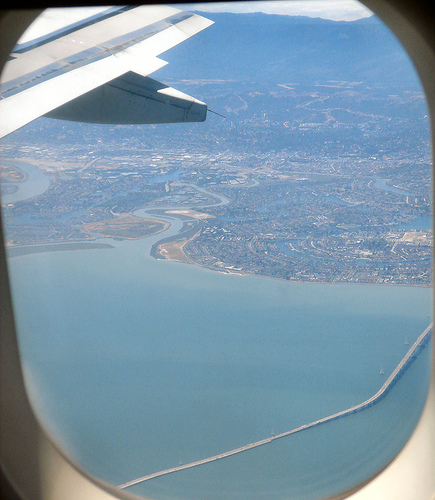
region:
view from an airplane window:
[16, 2, 424, 494]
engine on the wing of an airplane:
[47, 58, 212, 141]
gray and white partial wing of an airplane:
[2, 5, 219, 136]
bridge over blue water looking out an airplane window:
[117, 317, 433, 486]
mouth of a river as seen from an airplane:
[99, 219, 166, 263]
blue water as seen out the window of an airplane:
[118, 285, 364, 490]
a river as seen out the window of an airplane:
[136, 171, 232, 259]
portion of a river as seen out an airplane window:
[2, 158, 49, 210]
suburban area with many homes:
[194, 156, 423, 284]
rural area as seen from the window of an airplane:
[156, 26, 400, 148]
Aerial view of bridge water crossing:
[118, 301, 429, 493]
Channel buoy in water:
[373, 360, 388, 380]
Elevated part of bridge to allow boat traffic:
[397, 313, 429, 382]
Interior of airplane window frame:
[1, 229, 431, 499]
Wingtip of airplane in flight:
[1, 3, 229, 145]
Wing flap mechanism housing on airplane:
[42, 69, 218, 126]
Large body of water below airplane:
[13, 241, 430, 497]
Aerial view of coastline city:
[11, 143, 434, 295]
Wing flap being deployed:
[10, 4, 216, 148]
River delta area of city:
[62, 166, 434, 297]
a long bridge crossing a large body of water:
[105, 336, 414, 494]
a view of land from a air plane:
[105, 174, 381, 339]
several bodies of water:
[247, 181, 412, 265]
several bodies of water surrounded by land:
[247, 156, 411, 282]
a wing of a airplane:
[13, 20, 230, 159]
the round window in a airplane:
[12, 33, 419, 486]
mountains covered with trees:
[228, 19, 369, 96]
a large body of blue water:
[32, 285, 345, 468]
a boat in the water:
[374, 356, 396, 384]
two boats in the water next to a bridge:
[368, 324, 422, 397]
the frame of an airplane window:
[0, 1, 431, 497]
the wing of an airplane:
[0, 1, 236, 154]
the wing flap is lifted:
[0, 4, 201, 129]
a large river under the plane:
[18, 215, 426, 497]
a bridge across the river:
[111, 323, 430, 498]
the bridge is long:
[106, 325, 424, 492]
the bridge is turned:
[99, 323, 427, 486]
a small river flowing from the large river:
[136, 171, 234, 261]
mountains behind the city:
[85, 0, 412, 99]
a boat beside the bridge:
[398, 329, 412, 349]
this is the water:
[109, 302, 241, 377]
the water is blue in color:
[137, 324, 265, 379]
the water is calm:
[110, 328, 251, 403]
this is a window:
[12, 14, 433, 498]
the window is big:
[22, 1, 426, 498]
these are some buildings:
[234, 181, 378, 278]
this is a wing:
[31, 7, 213, 128]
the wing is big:
[24, 17, 141, 94]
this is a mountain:
[255, 7, 326, 75]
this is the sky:
[324, 0, 356, 18]